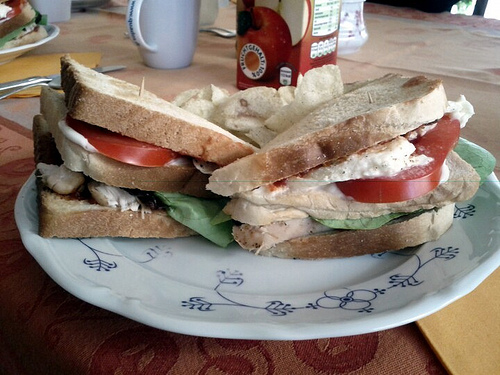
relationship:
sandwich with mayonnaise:
[213, 70, 463, 260] [58, 117, 96, 150]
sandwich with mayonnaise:
[31, 51, 258, 236] [58, 117, 96, 150]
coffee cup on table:
[125, 0, 201, 71] [55, 34, 496, 315]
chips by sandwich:
[210, 86, 297, 133] [103, 97, 455, 266]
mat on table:
[413, 259, 498, 374] [1, 1, 498, 373]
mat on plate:
[413, 259, 498, 374] [11, 163, 499, 344]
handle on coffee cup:
[125, 2, 157, 54] [125, 0, 201, 71]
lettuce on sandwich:
[154, 192, 222, 258] [27, 48, 264, 245]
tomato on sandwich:
[341, 120, 464, 212] [205, 57, 482, 259]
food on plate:
[32, 54, 471, 253] [10, 123, 497, 340]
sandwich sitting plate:
[31, 51, 258, 236] [10, 123, 497, 340]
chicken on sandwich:
[244, 173, 482, 243] [225, 64, 476, 258]